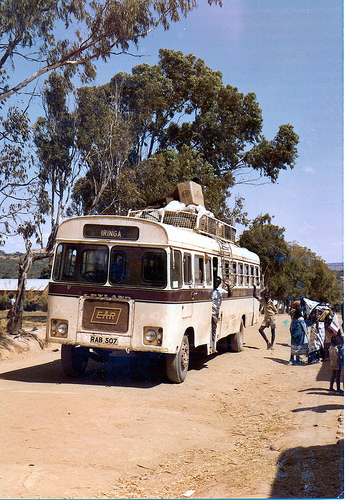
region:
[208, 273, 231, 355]
Man in white shirt with one arm raised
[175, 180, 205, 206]
Rectangle shaped cardboard box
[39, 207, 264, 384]
Tan and brown bus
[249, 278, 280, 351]
Man in tan shirt and shorts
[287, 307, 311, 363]
Woman in a blue dress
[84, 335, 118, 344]
License plate reading RAB 507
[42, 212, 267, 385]
Bus with a sign reading EAR on front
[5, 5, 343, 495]
Line of trees along a dusty road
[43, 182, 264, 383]
Bus with a fully loaded luggage rack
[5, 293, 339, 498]
Group of people standing by dirt road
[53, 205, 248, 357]
white bus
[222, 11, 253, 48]
white clouds in blue sky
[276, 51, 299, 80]
white clouds in blue sky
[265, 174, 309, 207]
white clouds in blue sky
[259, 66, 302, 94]
white clouds in blue sky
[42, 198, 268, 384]
Bus parked in the dirt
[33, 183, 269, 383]
Bus is parked in the dirt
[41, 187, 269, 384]
Bus parked on a dirt road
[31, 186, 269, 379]
Bus is parked on a dirt road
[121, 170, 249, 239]
Luggage on top of bus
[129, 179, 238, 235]
Luggage is on top of bus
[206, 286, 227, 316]
Man wearing a shirt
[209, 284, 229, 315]
Man is wearing a shirt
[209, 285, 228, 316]
Man is wearing a white shirt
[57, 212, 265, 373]
white bus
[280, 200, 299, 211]
white clouds in blue sky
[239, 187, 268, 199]
white clouds in blue sky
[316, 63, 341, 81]
white clouds in blue sky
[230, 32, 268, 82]
white clouds in blue sky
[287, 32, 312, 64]
white clouds in blue sky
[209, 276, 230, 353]
the man on the bus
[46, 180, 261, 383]
the bus parked on the dirt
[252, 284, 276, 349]
the man leaning on the bus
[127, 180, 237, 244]
the stuff on the top of the bus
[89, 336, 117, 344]
the license plate on the bus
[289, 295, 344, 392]
the group of people near the bus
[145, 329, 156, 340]
the headlight on the bus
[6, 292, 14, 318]
the person behind the tree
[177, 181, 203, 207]
the cardboard box on the bus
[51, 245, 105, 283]
window of a bus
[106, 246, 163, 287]
window of a bus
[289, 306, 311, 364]
a woman is standing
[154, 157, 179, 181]
green leaves on the tree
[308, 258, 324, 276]
green leaves on the tree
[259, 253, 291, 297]
green leaves on the tree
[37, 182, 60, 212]
green leaves on the tree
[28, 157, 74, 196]
green leaves on the tree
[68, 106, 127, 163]
green leaves on the tree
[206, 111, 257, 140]
green leaves on the tree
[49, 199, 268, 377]
old white passenger bus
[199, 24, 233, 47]
white clouds in blue sky